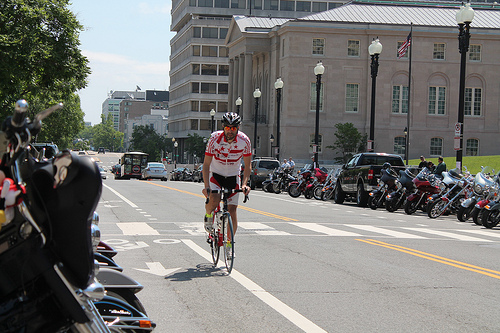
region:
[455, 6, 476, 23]
The glass globes around the street lights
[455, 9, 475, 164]
A street light that is not lit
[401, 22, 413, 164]
An american flag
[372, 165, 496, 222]
Motorcycles all lined up on the street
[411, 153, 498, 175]
A green grass feild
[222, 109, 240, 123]
A bikers helmet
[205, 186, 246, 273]
A street bicycle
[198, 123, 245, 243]
A man riding a bike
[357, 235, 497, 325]
double yellow lines in the street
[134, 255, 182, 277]
A white painted arrow in the street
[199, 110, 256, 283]
Man is riding a bike away from the buildings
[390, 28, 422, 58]
American flag is raised on flag post on right side of street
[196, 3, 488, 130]
7 light posts om right side of street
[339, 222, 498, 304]
Yellow double lines down middle of street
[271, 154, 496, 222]
9 motorcycles parked around a black truck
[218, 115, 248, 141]
Bicycle rider is wearing a helmet and orange sunglasses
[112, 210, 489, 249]
White painted crosswalk behind the rider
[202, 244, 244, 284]
Rider is riding on the bicycle white outline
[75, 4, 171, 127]
Weather is sunny with a few clouds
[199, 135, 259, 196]
Man is wearing a white and red shirt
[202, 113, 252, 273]
Man riding a bike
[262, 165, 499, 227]
Some motorcycles are parked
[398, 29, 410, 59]
American flag is waving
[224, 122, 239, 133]
The glasses are orange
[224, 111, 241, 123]
Helmet is black and white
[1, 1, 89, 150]
Tree hangs over the road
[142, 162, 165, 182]
Car driving on street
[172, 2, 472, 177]
Light poles on sidewalk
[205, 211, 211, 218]
The sock is yellow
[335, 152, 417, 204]
A truck is parked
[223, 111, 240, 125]
a helmet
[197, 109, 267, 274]
the man is riding a bike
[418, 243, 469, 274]
the yellow line in the street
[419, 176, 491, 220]
motorcycles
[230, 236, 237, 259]
front tire of the bike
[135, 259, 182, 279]
an arrow in the street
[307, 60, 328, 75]
a street light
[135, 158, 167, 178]
a car on the street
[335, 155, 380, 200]
a black truck that is parked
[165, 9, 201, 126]
a tall building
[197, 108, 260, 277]
Cyclist on the street.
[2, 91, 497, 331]
Motorcycles lined up along the street.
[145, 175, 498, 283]
Yellow lines on the street.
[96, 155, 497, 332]
White lines on the street.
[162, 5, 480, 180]
Numerous lights along the street.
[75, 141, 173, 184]
Cars in the background.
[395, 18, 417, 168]
American flag on a pole.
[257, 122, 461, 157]
Signs on the light poles.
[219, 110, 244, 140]
Cyclists black helmet on head.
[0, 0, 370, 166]
Trees in the background.